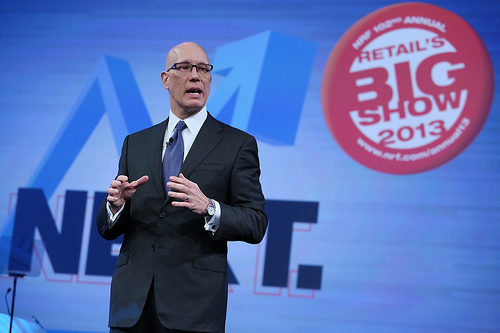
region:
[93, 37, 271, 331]
a man standing and talking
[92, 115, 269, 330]
the man is wearing a suit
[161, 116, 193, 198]
he has a blue tie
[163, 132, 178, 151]
he is wearing a microphone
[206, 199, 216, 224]
he is wearing a watch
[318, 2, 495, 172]
a red sign on the wall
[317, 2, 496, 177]
the red sign is round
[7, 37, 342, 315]
blue letters on the wall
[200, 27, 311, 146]
an arrow pointing up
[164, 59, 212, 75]
the man is wearing glasses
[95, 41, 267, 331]
Man wearing black suit jacket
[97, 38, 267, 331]
Man wearing white button down shirt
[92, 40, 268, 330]
Man wearing purple tie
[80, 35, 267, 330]
Man wearing silver watch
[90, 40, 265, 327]
Man wearing wedding ring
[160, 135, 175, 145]
Black microphone on purple tie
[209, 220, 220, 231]
Button on sleeve of button down shirt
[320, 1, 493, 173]
Red circular sign behind man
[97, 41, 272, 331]
Man wearing black pants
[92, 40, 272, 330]
Man holding hands up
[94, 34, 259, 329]
Man standing with his arms in front of him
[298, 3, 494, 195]
Large red circle with a white interior that has red writing on it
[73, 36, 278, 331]
Man in a black suit with a white shirt and blue tie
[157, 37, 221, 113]
Bald man's head wearing thick black glasses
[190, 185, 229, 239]
A black watch with a white face on a man's wrist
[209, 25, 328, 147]
Large blue arrow with shadow on a darker blue background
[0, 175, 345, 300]
Blue words that say Next on a screen behind a man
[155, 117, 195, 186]
Blue tie on a white shirt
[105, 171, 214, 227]
A person's hands gesturing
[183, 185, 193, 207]
Golden ring on a man's finger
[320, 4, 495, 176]
red circle on the screen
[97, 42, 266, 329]
man in suit giving a speech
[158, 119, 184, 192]
navy blue tie on the man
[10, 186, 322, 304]
dark blue text on the screen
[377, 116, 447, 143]
the year 2013 on the screen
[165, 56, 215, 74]
eye glasses on the man in the suit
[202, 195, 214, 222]
watch on the man's wrist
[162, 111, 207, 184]
white collared shirt on the man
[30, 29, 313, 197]
blue arrow on the screen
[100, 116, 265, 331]
black suit jacket on the man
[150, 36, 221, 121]
man with no hair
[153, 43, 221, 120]
bald man wearing glasses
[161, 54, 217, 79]
black thick rimmed glasses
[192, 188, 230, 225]
silver round watch on wrist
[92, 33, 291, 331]
man wearing suit and tie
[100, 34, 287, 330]
man wearing black jacket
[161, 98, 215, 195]
white collared shirt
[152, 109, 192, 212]
plain purple tie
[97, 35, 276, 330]
man wearing a purple tie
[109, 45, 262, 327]
man standing in front of blue screen